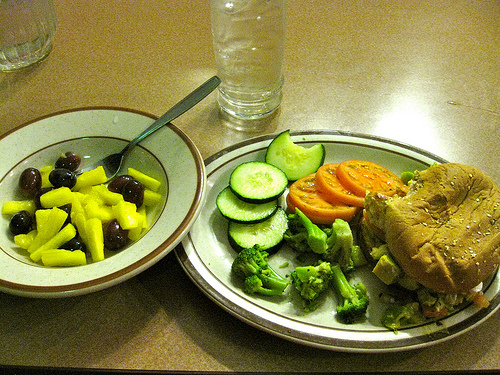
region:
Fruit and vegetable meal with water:
[5, 1, 490, 352]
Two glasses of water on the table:
[1, 0, 300, 126]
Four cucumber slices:
[211, 120, 331, 262]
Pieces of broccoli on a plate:
[222, 201, 407, 328]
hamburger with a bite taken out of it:
[353, 152, 498, 337]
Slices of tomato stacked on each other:
[281, 149, 411, 231]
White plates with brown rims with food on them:
[0, 98, 499, 355]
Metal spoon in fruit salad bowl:
[61, 60, 225, 201]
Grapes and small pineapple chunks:
[2, 137, 169, 274]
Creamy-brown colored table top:
[15, 11, 478, 155]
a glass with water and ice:
[196, 0, 320, 130]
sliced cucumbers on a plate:
[219, 134, 336, 252]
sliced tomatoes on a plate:
[287, 149, 399, 226]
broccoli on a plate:
[241, 219, 386, 314]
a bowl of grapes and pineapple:
[0, 110, 184, 282]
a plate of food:
[153, 120, 478, 357]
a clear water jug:
[0, 3, 71, 71]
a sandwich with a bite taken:
[351, 142, 483, 307]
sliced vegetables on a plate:
[226, 145, 401, 259]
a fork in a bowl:
[67, 60, 228, 202]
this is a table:
[308, 15, 450, 121]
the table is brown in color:
[312, 18, 376, 61]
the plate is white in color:
[152, 220, 171, 231]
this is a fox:
[130, 95, 200, 140]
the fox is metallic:
[170, 80, 205, 110]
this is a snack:
[411, 190, 491, 280]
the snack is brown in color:
[415, 200, 450, 242]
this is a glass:
[227, 55, 267, 105]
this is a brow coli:
[290, 260, 325, 295]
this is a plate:
[152, 206, 183, 237]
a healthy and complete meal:
[6, 6, 490, 360]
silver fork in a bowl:
[78, 141, 146, 178]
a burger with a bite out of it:
[373, 169, 498, 303]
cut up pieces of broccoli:
[292, 216, 367, 316]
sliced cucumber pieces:
[216, 157, 288, 245]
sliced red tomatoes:
[282, 157, 394, 212]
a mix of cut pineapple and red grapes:
[1, 151, 143, 266]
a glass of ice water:
[206, 4, 287, 128]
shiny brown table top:
[301, 11, 486, 118]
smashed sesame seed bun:
[415, 180, 496, 267]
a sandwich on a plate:
[371, 151, 494, 339]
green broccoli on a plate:
[212, 222, 377, 319]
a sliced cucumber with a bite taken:
[258, 128, 324, 178]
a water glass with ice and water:
[194, 1, 289, 129]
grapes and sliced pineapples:
[2, 107, 207, 286]